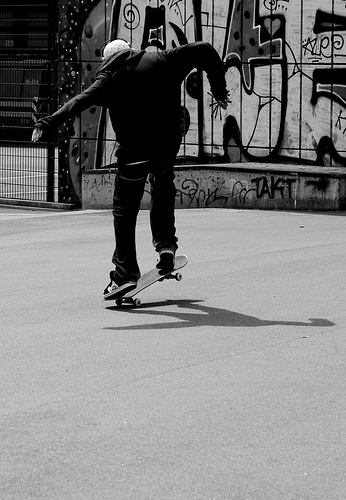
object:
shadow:
[99, 299, 337, 330]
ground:
[0, 201, 346, 500]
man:
[29, 37, 229, 297]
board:
[103, 254, 190, 306]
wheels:
[135, 298, 142, 306]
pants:
[108, 143, 180, 283]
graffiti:
[89, 0, 346, 165]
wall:
[59, 0, 346, 213]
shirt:
[36, 42, 226, 157]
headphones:
[99, 37, 132, 63]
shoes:
[102, 268, 138, 301]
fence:
[2, 0, 76, 210]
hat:
[103, 40, 129, 60]